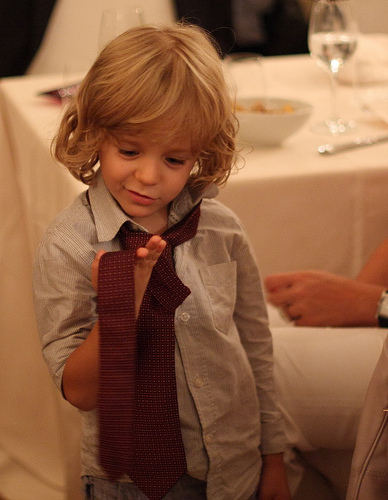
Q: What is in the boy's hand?
A: A tie.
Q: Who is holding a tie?
A: A young boy.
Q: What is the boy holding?
A: A tie.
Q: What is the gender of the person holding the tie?
A: Male.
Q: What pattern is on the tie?
A: Dots.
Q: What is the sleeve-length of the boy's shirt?
A: Long-sleeved.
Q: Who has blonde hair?
A: A young boy.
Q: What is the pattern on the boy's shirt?
A: Striped.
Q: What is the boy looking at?
A: A tie.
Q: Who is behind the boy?
A: A female.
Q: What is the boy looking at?
A: His tie.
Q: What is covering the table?
A: A white tablecloth.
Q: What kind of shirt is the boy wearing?
A: A dress shirt.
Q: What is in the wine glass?
A: A clear liquid.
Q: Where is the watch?
A: A person's left wrist.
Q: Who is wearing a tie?
A: A child.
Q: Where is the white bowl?
A: On the tablecloth.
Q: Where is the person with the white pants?
A: Behind the boy.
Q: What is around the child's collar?
A: A red tie.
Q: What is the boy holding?
A: His tie.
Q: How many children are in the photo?
A: 1.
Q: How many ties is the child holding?
A: 1.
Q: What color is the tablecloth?
A: White.